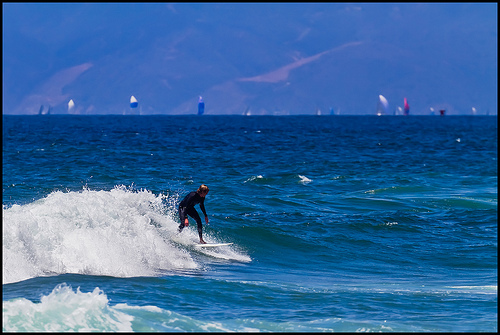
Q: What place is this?
A: It is an ocean.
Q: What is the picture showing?
A: It is showing an ocean.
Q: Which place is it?
A: It is an ocean.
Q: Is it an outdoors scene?
A: Yes, it is outdoors.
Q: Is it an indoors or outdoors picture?
A: It is outdoors.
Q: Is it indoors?
A: No, it is outdoors.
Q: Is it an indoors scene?
A: No, it is outdoors.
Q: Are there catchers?
A: No, there are no catchers.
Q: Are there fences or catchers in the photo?
A: No, there are no catchers or fences.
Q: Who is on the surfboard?
A: The man is on the surfboard.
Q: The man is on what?
A: The man is on the surfboard.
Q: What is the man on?
A: The man is on the surfboard.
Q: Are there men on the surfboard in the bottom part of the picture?
A: Yes, there is a man on the surfboard.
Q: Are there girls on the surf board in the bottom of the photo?
A: No, there is a man on the surfboard.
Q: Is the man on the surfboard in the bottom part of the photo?
A: Yes, the man is on the surfboard.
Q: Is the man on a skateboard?
A: No, the man is on the surfboard.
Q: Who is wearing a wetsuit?
A: The man is wearing a wetsuit.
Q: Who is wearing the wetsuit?
A: The man is wearing a wetsuit.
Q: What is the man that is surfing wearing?
A: The man is wearing a wetsuit.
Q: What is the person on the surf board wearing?
A: The man is wearing a wetsuit.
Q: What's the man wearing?
A: The man is wearing a wetsuit.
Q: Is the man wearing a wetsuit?
A: Yes, the man is wearing a wetsuit.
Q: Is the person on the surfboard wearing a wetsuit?
A: Yes, the man is wearing a wetsuit.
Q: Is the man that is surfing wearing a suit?
A: No, the man is wearing a wetsuit.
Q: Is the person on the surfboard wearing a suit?
A: No, the man is wearing a wetsuit.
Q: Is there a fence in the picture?
A: No, there are no fences.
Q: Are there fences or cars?
A: No, there are no fences or cars.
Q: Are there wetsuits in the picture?
A: Yes, there is a wetsuit.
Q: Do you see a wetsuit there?
A: Yes, there is a wetsuit.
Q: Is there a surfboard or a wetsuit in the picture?
A: Yes, there is a wetsuit.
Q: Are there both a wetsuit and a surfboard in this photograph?
A: Yes, there are both a wetsuit and a surfboard.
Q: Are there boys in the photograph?
A: No, there are no boys.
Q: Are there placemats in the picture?
A: No, there are no placemats.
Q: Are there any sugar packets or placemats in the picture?
A: No, there are no placemats or sugar packets.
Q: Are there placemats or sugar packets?
A: No, there are no placemats or sugar packets.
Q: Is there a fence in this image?
A: No, there are no fences.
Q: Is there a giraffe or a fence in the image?
A: No, there are no fences or giraffes.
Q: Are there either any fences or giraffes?
A: No, there are no fences or giraffes.